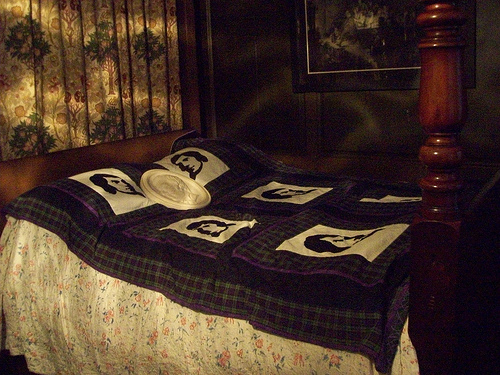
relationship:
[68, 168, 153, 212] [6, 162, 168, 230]
picture on pillow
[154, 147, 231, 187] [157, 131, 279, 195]
picture on pillow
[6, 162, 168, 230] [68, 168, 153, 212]
pillow has picture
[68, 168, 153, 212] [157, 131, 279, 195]
picture on pillow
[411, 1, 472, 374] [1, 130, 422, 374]
wood on bed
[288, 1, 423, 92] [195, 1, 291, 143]
picture on wall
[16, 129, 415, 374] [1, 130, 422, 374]
blanket on bed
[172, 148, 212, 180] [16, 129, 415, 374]
man on blanket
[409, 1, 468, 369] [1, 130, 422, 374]
post on bed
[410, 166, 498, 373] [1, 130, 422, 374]
headboard on bed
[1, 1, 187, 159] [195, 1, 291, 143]
curtain on wall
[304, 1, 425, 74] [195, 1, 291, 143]
picture on wall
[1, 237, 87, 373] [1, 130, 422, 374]
blanket on bed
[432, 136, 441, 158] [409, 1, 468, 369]
reflection on post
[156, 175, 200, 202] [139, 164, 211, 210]
head on coin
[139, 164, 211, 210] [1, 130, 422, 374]
coin on bed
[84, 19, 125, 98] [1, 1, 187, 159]
tree on curtain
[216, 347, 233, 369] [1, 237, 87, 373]
flower on blanket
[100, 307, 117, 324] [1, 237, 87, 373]
flower on blanket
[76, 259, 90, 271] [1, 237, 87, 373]
flower on blanket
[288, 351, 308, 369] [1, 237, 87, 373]
flower on blanket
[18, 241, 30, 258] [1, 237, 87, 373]
flower on blanket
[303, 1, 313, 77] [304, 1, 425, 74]
line on picture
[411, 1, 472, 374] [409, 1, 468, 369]
wood bed post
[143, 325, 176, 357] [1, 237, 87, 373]
flower on blanket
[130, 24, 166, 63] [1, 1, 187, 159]
tree on curtain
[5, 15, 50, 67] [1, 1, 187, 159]
tree on curtain